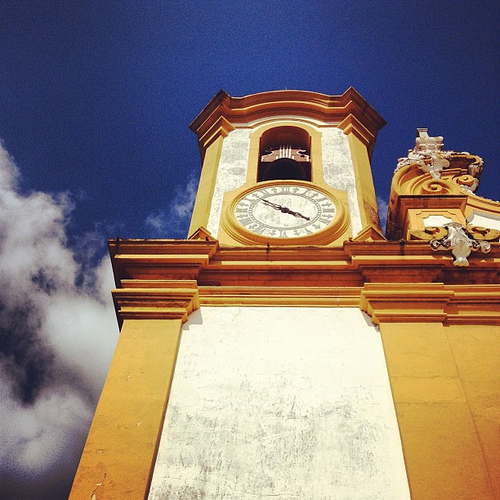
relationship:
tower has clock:
[165, 65, 392, 375] [223, 170, 355, 252]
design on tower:
[322, 132, 351, 182] [65, 82, 497, 497]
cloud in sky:
[3, 368, 95, 493] [0, 1, 497, 246]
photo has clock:
[2, 2, 484, 498] [221, 172, 346, 245]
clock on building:
[221, 179, 348, 244] [55, 68, 498, 498]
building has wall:
[55, 68, 498, 498] [142, 306, 412, 498]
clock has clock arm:
[216, 174, 353, 246] [254, 192, 279, 212]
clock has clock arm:
[216, 174, 353, 246] [286, 206, 312, 222]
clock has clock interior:
[221, 168, 356, 273] [228, 183, 338, 238]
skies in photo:
[101, 31, 195, 79] [2, 2, 484, 498]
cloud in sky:
[1, 140, 87, 340] [1, 0, 490, 497]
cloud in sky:
[3, 368, 95, 493] [1, 0, 490, 497]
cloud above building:
[33, 291, 119, 378] [55, 68, 498, 498]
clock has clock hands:
[221, 179, 348, 244] [259, 195, 312, 221]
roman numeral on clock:
[278, 183, 290, 193] [221, 179, 349, 245]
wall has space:
[142, 306, 412, 498] [211, 351, 354, 473]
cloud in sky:
[1, 140, 87, 340] [30, 68, 124, 193]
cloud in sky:
[2, 250, 121, 497] [30, 68, 124, 193]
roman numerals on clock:
[219, 172, 351, 246] [209, 170, 371, 242]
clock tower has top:
[168, 73, 399, 263] [181, 75, 393, 149]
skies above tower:
[0, 0, 500, 219] [182, 78, 390, 249]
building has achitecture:
[55, 68, 498, 498] [385, 122, 496, 267]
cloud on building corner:
[33, 291, 119, 378] [81, 221, 153, 309]